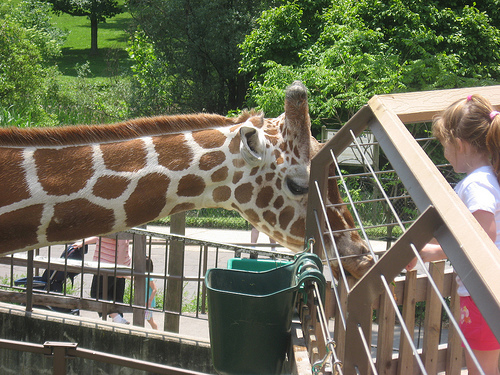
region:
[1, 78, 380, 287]
A giraffe's head and neck.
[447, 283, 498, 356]
Red colored shorts on the girl.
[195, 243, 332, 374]
Green colored food buckets for the giraffe.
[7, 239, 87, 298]
A baby stroller sitting on the sidewalk.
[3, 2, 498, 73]
Trees with green leaves in the background.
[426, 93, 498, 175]
The girls hair is pulled back in a ponytail.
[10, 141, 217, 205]
Brown and white pattern on the neck of the giraffe.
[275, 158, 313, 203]
The giraffe's eye is looking downward.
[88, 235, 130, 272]
A person wearing a pink striped shirt.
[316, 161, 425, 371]
Fencing keeping the giraffe inside the enclosure.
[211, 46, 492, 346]
a girl and a giraffe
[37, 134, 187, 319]
woman child and stroller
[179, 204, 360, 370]
the food bins are green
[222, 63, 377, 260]
the giraffe has brown spots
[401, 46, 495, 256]
the girl is blonde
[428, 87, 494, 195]
her hair is a ponytail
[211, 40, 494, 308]
the girl is in the lookout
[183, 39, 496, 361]
the giraffe is with the girl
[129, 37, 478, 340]
the giraffe is in a zoo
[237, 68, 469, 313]
the railing is wood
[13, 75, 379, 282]
giraffe being fed by little girl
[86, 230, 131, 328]
woman pushing baby stroller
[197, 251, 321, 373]
giraffe's food and water buckets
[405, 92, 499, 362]
little girl feeding giraffe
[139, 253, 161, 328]
little girl with green top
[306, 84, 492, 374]
wooden railing around viewing area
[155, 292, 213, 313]
green plants along sidewalk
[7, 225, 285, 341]
fence around giraffe's pen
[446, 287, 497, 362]
little girls' red shorts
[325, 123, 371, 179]
white sign in background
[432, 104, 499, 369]
little girl with a pony tail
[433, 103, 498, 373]
little girl with pink shorts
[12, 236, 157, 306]
a parent, child and stroller behind the giraffe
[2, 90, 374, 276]
giraffe eating by the girl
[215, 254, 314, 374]
two green feed buckets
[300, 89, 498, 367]
wooden railing by the girl in pink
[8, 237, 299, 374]
railing behind giraffe by person with stroller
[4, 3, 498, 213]
green trees in the background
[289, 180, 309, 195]
the giraffe's right eye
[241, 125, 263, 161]
the giraffe's ear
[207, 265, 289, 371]
a green bucket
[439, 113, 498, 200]
a girl standing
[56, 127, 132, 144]
the hair on the giraffe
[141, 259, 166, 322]
a child walking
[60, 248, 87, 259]
a stroller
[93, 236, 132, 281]
a person pushing a stroller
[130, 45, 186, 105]
the leaves are green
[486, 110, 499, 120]
a pink hair tie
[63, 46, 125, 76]
a shadow on the grass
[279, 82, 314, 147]
horns on the giraffe